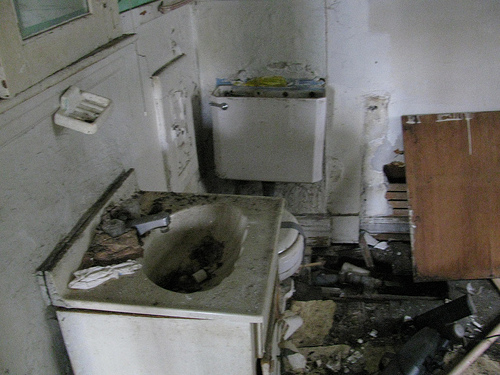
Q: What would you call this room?
A: A bathroom.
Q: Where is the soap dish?
A: On the wall above the sink.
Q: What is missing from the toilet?
A: The tank cover.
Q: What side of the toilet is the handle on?
A: The left.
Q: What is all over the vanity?
A: Dirt.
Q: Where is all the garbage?
A: On the floor.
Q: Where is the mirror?
A: On the wall.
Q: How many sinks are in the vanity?
A: One.